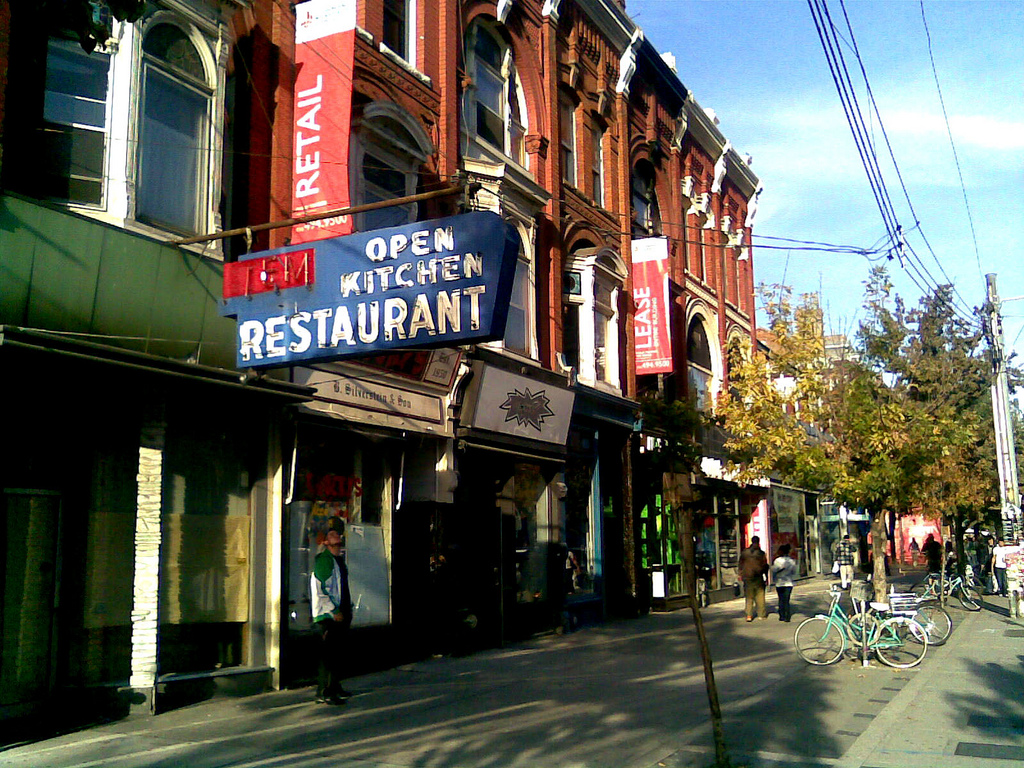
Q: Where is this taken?
A: Along a city street.